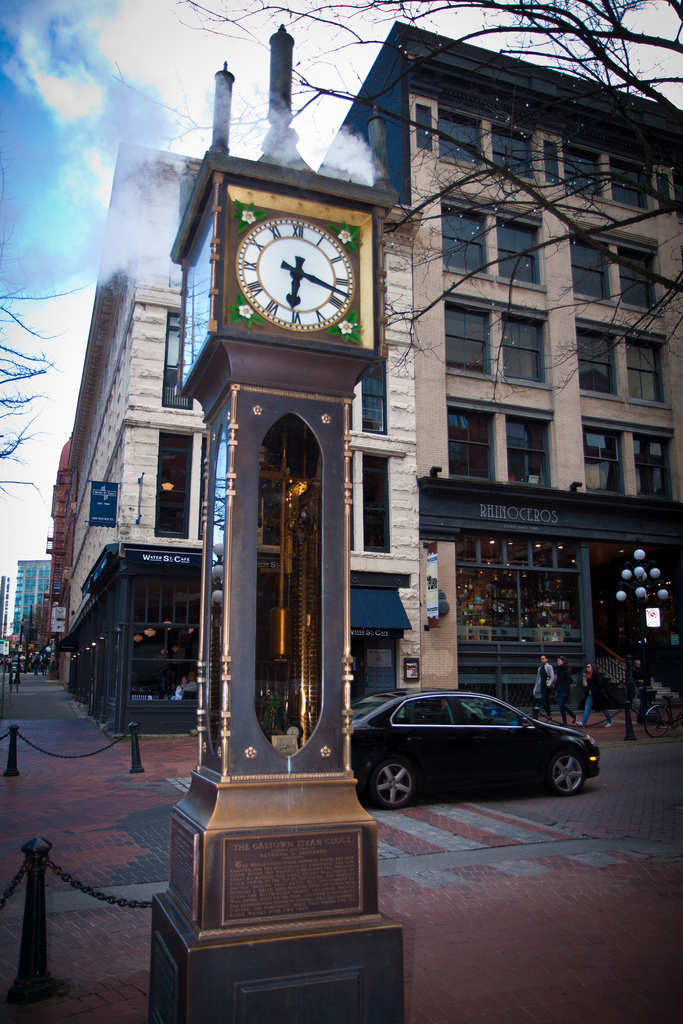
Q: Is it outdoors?
A: Yes, it is outdoors.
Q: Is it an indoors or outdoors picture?
A: It is outdoors.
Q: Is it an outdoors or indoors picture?
A: It is outdoors.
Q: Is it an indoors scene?
A: No, it is outdoors.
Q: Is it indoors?
A: No, it is outdoors.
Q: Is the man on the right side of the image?
A: Yes, the man is on the right of the image.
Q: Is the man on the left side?
A: No, the man is on the right of the image.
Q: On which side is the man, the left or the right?
A: The man is on the right of the image.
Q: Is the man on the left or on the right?
A: The man is on the right of the image.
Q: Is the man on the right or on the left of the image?
A: The man is on the right of the image.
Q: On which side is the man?
A: The man is on the right of the image.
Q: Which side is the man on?
A: The man is on the right of the image.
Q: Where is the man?
A: The man is on the sidewalk.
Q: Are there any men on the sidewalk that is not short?
A: Yes, there is a man on the sidewalk.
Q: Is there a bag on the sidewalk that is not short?
A: No, there is a man on the sidewalk.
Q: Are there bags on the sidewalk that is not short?
A: No, there is a man on the sidewalk.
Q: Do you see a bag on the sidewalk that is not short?
A: No, there is a man on the sidewalk.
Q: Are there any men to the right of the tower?
A: Yes, there is a man to the right of the tower.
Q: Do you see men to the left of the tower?
A: No, the man is to the right of the tower.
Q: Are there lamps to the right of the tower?
A: No, there is a man to the right of the tower.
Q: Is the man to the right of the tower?
A: Yes, the man is to the right of the tower.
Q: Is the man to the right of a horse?
A: No, the man is to the right of the tower.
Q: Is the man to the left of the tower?
A: No, the man is to the right of the tower.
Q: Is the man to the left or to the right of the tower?
A: The man is to the right of the tower.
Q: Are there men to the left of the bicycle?
A: Yes, there is a man to the left of the bicycle.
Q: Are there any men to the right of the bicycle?
A: No, the man is to the left of the bicycle.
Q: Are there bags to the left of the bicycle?
A: No, there is a man to the left of the bicycle.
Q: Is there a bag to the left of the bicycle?
A: No, there is a man to the left of the bicycle.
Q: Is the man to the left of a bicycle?
A: Yes, the man is to the left of a bicycle.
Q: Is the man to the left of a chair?
A: No, the man is to the left of a bicycle.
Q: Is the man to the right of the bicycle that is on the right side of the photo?
A: No, the man is to the left of the bicycle.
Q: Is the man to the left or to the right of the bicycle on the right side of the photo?
A: The man is to the left of the bicycle.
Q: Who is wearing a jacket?
A: The man is wearing a jacket.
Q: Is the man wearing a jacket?
A: Yes, the man is wearing a jacket.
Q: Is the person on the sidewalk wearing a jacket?
A: Yes, the man is wearing a jacket.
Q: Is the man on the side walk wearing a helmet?
A: No, the man is wearing a jacket.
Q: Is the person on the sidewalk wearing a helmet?
A: No, the man is wearing a jacket.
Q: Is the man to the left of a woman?
A: Yes, the man is to the left of a woman.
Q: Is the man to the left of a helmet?
A: No, the man is to the left of a woman.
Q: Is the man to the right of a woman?
A: No, the man is to the left of a woman.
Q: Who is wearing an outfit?
A: The man is wearing an outfit.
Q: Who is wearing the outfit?
A: The man is wearing an outfit.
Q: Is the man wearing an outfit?
A: Yes, the man is wearing an outfit.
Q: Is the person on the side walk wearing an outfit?
A: Yes, the man is wearing an outfit.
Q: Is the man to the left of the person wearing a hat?
A: No, the man is wearing an outfit.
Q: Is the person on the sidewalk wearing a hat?
A: No, the man is wearing an outfit.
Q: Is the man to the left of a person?
A: Yes, the man is to the left of a person.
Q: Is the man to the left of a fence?
A: No, the man is to the left of a person.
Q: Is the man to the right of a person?
A: No, the man is to the left of a person.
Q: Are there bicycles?
A: Yes, there is a bicycle.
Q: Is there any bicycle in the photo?
A: Yes, there is a bicycle.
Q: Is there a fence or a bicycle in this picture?
A: Yes, there is a bicycle.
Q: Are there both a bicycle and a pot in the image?
A: No, there is a bicycle but no pots.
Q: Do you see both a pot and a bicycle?
A: No, there is a bicycle but no pots.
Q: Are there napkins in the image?
A: No, there are no napkins.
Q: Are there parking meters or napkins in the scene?
A: No, there are no napkins or parking meters.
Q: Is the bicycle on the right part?
A: Yes, the bicycle is on the right of the image.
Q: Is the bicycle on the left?
A: No, the bicycle is on the right of the image.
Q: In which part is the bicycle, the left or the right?
A: The bicycle is on the right of the image.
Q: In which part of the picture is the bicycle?
A: The bicycle is on the right of the image.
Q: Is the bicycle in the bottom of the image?
A: Yes, the bicycle is in the bottom of the image.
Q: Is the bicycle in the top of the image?
A: No, the bicycle is in the bottom of the image.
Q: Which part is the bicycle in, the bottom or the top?
A: The bicycle is in the bottom of the image.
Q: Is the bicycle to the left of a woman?
A: No, the bicycle is to the right of a woman.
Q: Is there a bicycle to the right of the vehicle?
A: Yes, there is a bicycle to the right of the vehicle.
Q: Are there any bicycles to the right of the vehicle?
A: Yes, there is a bicycle to the right of the vehicle.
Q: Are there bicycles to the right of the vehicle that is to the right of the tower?
A: Yes, there is a bicycle to the right of the vehicle.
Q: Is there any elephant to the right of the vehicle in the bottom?
A: No, there is a bicycle to the right of the vehicle.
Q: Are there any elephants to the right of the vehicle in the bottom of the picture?
A: No, there is a bicycle to the right of the vehicle.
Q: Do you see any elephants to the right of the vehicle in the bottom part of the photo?
A: No, there is a bicycle to the right of the vehicle.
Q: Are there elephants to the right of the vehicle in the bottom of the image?
A: No, there is a bicycle to the right of the vehicle.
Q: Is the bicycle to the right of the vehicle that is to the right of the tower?
A: Yes, the bicycle is to the right of the vehicle.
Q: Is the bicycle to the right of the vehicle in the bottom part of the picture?
A: Yes, the bicycle is to the right of the vehicle.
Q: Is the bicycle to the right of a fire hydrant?
A: No, the bicycle is to the right of the vehicle.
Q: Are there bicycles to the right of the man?
A: Yes, there is a bicycle to the right of the man.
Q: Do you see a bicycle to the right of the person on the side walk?
A: Yes, there is a bicycle to the right of the man.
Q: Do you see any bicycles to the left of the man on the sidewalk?
A: No, the bicycle is to the right of the man.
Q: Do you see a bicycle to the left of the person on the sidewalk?
A: No, the bicycle is to the right of the man.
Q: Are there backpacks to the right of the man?
A: No, there is a bicycle to the right of the man.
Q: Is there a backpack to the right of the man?
A: No, there is a bicycle to the right of the man.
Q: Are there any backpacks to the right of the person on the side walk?
A: No, there is a bicycle to the right of the man.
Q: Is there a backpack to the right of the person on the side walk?
A: No, there is a bicycle to the right of the man.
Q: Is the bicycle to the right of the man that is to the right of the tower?
A: Yes, the bicycle is to the right of the man.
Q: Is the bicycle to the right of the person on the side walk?
A: Yes, the bicycle is to the right of the man.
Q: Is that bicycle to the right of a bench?
A: No, the bicycle is to the right of the man.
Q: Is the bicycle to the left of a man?
A: No, the bicycle is to the right of a man.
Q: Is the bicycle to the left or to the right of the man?
A: The bicycle is to the right of the man.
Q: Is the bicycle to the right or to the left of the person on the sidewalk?
A: The bicycle is to the right of the man.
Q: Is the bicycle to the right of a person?
A: Yes, the bicycle is to the right of a person.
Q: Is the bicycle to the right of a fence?
A: No, the bicycle is to the right of a person.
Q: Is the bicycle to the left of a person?
A: No, the bicycle is to the right of a person.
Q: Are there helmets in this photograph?
A: No, there are no helmets.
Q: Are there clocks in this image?
A: Yes, there is a clock.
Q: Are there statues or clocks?
A: Yes, there is a clock.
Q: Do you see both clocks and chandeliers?
A: No, there is a clock but no chandeliers.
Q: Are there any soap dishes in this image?
A: No, there are no soap dishes.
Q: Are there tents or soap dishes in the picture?
A: No, there are no soap dishes or tents.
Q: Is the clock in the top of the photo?
A: Yes, the clock is in the top of the image.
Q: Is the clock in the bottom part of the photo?
A: No, the clock is in the top of the image.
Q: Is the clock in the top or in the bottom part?
A: The clock is in the top of the image.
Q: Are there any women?
A: Yes, there is a woman.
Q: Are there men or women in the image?
A: Yes, there is a woman.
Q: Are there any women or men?
A: Yes, there is a woman.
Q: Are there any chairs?
A: No, there are no chairs.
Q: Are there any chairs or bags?
A: No, there are no chairs or bags.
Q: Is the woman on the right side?
A: Yes, the woman is on the right of the image.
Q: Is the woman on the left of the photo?
A: No, the woman is on the right of the image.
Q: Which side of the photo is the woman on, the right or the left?
A: The woman is on the right of the image.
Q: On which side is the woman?
A: The woman is on the right of the image.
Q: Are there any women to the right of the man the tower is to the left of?
A: Yes, there is a woman to the right of the man.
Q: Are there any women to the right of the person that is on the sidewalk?
A: Yes, there is a woman to the right of the man.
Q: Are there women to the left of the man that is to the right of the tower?
A: No, the woman is to the right of the man.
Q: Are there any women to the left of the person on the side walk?
A: No, the woman is to the right of the man.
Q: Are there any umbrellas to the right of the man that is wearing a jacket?
A: No, there is a woman to the right of the man.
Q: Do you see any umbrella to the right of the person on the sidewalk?
A: No, there is a woman to the right of the man.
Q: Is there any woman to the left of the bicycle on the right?
A: Yes, there is a woman to the left of the bicycle.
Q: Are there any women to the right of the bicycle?
A: No, the woman is to the left of the bicycle.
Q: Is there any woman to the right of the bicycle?
A: No, the woman is to the left of the bicycle.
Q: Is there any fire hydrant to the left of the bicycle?
A: No, there is a woman to the left of the bicycle.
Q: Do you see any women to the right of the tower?
A: Yes, there is a woman to the right of the tower.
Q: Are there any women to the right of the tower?
A: Yes, there is a woman to the right of the tower.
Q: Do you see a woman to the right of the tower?
A: Yes, there is a woman to the right of the tower.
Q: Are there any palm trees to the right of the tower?
A: No, there is a woman to the right of the tower.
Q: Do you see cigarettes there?
A: No, there are no cigarettes.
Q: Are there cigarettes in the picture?
A: No, there are no cigarettes.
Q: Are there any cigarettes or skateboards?
A: No, there are no cigarettes or skateboards.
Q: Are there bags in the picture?
A: No, there are no bags.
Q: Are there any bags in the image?
A: No, there are no bags.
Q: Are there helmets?
A: No, there are no helmets.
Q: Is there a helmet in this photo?
A: No, there are no helmets.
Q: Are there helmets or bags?
A: No, there are no helmets or bags.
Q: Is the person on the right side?
A: Yes, the person is on the right of the image.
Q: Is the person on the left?
A: No, the person is on the right of the image.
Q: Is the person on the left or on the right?
A: The person is on the right of the image.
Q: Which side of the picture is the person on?
A: The person is on the right of the image.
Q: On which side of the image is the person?
A: The person is on the right of the image.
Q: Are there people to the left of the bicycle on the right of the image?
A: Yes, there is a person to the left of the bicycle.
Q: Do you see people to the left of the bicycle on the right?
A: Yes, there is a person to the left of the bicycle.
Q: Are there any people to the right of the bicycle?
A: No, the person is to the left of the bicycle.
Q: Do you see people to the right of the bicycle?
A: No, the person is to the left of the bicycle.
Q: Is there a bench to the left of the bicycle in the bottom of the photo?
A: No, there is a person to the left of the bicycle.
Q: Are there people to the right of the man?
A: Yes, there is a person to the right of the man.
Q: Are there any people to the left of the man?
A: No, the person is to the right of the man.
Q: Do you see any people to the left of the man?
A: No, the person is to the right of the man.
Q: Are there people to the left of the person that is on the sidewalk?
A: No, the person is to the right of the man.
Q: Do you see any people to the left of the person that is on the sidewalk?
A: No, the person is to the right of the man.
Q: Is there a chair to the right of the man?
A: No, there is a person to the right of the man.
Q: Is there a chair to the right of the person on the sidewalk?
A: No, there is a person to the right of the man.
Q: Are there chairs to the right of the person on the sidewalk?
A: No, there is a person to the right of the man.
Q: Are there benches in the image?
A: No, there are no benches.